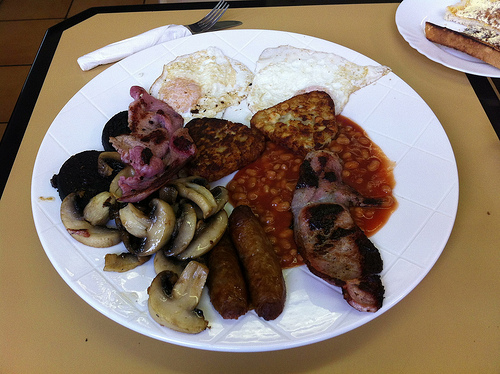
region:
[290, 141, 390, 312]
Ham is on a plate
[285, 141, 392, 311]
Ham has black char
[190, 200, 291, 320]
Sausages are on a plate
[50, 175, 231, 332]
Mushrooms are on a plate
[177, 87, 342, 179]
Hash browns are on a plate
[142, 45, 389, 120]
Eggs are on a plate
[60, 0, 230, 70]
Fork is on a table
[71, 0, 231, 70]
Fork is wrapped in a napkin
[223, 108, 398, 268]
Beans are on a plate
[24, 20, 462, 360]
Food is on a white plate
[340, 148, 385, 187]
Beans in the photo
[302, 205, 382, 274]
Meat in the photo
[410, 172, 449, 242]
Plate in the photo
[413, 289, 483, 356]
Table in the photo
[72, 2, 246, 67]
Fork in the photo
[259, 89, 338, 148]
Pizza in the photo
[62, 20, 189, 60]
Serviette in the photo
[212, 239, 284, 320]
Sausages in the photo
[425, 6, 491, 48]
Bread in the photo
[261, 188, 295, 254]
Sauce in the photo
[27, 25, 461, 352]
A white plate filled with breakfast food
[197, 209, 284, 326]
Cooked sausages on a plate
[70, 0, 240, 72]
Silverware wrapped in a napkin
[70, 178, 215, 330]
Brown cooked mushrooms on a plate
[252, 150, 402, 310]
Pork and baked beans on a plate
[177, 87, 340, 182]
Brown, cookes hashbrowns with baked beans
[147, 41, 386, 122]
Cooked eggs on a white plate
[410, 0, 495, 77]
Toast on a white plate with a bite missing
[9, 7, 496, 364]
White plate of breakfast food on a table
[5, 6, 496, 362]
Breakfast served at a restaraunt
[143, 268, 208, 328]
mushroom on the plate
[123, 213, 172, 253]
mushroom on the plate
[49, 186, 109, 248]
mushroom on the plate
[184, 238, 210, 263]
mushroom on the plate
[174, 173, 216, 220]
mushroom on the plate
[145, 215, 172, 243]
mushroom on the plate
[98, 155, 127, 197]
mushroom on the plate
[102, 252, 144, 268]
mushroom on the plate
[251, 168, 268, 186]
baked beans on plate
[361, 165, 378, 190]
baked beans on plate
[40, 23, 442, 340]
white plate with food on it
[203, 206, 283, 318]
two pieces on white plate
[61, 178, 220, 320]
mushrooms on white plate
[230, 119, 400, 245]
baked beans on white plate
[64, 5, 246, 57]
fork and knife wrapped in white napkin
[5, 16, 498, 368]
table plate of food is on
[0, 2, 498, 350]
tan table with black edges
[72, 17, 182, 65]
white napkin wrapped around silverware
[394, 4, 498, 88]
toast on white plate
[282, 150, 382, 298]
piece of meat on white plate